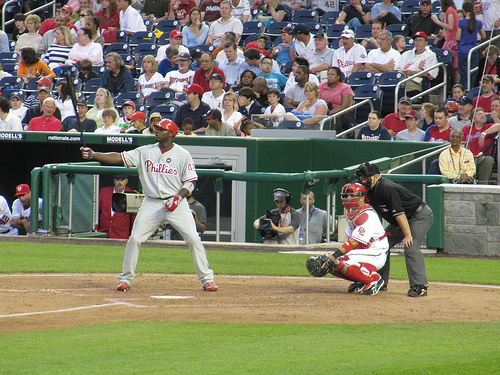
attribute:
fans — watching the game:
[2, 4, 474, 134]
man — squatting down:
[310, 175, 395, 298]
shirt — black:
[368, 172, 426, 219]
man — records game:
[246, 177, 300, 247]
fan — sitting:
[313, 57, 356, 109]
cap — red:
[408, 26, 429, 46]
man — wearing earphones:
[255, 183, 300, 233]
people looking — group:
[287, 27, 500, 157]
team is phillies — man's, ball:
[73, 117, 231, 301]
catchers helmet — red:
[304, 182, 396, 308]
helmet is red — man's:
[151, 117, 180, 153]